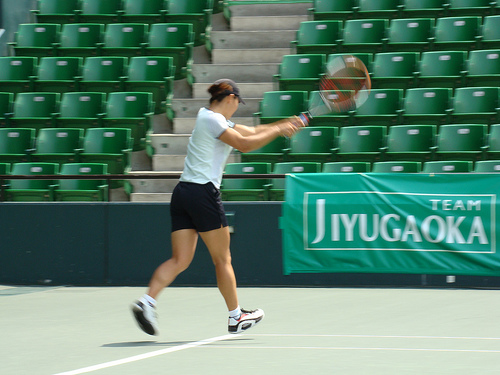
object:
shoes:
[127, 294, 162, 338]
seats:
[371, 49, 419, 75]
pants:
[169, 182, 229, 232]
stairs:
[130, 3, 309, 207]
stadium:
[0, 0, 497, 375]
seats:
[466, 50, 500, 78]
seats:
[373, 160, 419, 174]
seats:
[424, 159, 473, 172]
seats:
[453, 86, 499, 116]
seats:
[402, 86, 452, 114]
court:
[0, 201, 500, 374]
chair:
[389, 123, 434, 152]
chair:
[338, 125, 387, 156]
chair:
[291, 127, 338, 151]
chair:
[436, 122, 486, 153]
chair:
[403, 87, 452, 115]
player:
[128, 79, 304, 336]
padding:
[0, 204, 112, 285]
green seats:
[225, 0, 500, 200]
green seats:
[0, 0, 211, 201]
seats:
[436, 14, 480, 43]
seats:
[472, 160, 499, 171]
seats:
[122, 56, 172, 82]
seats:
[16, 21, 61, 45]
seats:
[7, 161, 56, 188]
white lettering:
[485, 54, 499, 63]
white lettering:
[456, 128, 469, 136]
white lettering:
[99, 61, 112, 65]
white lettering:
[54, 132, 68, 140]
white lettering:
[27, 166, 42, 173]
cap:
[208, 78, 246, 104]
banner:
[278, 173, 499, 277]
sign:
[304, 192, 497, 254]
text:
[426, 194, 479, 211]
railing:
[7, 170, 121, 178]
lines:
[58, 331, 240, 374]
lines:
[201, 346, 396, 354]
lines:
[243, 332, 436, 342]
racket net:
[319, 67, 368, 102]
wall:
[1, 199, 499, 287]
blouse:
[179, 107, 235, 189]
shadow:
[98, 338, 255, 348]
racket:
[301, 56, 369, 124]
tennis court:
[4, 283, 497, 373]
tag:
[99, 60, 111, 68]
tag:
[436, 54, 452, 61]